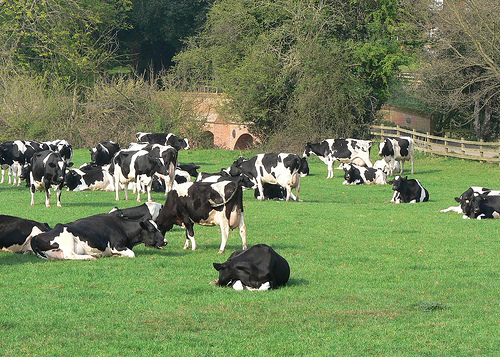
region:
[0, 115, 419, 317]
this is a herd of cow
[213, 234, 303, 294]
the cow is sleeping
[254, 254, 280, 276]
the cow is black in color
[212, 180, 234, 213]
this is the tail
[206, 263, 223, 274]
this is the ear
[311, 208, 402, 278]
the grass are short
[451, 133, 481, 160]
the fence is wooden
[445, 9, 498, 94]
the tree is thorny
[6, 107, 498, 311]
white and black cows in field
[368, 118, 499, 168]
wood fence along grass field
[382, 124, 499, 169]
path beside grass field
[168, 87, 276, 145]
bridge on backside of field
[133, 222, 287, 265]
cow shadows on the grass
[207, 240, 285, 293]
blac and white cow curled up on grass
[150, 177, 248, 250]
black and white cow swinging his tail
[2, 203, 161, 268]
three black and white cows laying together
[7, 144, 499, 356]
grass field cows are standing on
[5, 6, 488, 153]
trees along field and path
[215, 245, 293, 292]
The cow is lying on the grass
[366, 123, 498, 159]
A fence behind the cows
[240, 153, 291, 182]
The cow has black and white spots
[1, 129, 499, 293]
Cows in the grassy field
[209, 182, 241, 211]
The tail of the cow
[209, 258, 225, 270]
The ear of the cow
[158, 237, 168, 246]
The nose of the cow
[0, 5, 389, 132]
Trees near the grassy field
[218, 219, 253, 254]
The back legs of the cow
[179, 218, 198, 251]
The front legs of the cow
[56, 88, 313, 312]
Cows on the field.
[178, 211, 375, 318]
Black and white cow on the field.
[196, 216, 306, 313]
Black and white cow.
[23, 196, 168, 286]
Cow.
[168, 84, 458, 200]
Bridge in the background.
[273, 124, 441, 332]
Green grass on the field.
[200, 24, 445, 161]
Trees in the background.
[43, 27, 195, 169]
branches on the tree.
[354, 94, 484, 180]
Fence in the background.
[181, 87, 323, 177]
Brick bridge in the background.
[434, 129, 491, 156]
brown wooden fence on right of photo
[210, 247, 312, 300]
black cow on grass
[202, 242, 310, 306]
black cow looking away from camera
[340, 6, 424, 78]
green leaves on tree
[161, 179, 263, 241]
black and white standing cow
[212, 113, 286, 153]
half circle brick bridge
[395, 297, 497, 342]
grassy area on right of photo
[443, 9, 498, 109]
brown tree with no leaves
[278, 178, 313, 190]
pink udders on cow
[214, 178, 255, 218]
black and white cow's tail